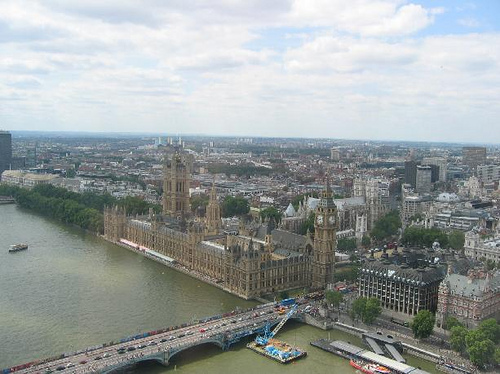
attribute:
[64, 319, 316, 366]
bridge — busy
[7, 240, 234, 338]
river — volumous, green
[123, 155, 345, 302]
castle — majestic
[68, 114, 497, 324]
city — london, large, aerial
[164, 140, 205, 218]
tower — high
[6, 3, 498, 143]
sky — overcast, cloudy, blue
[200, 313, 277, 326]
cars — crossing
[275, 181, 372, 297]
building — gray, brick, old, crowded, dark, parliament house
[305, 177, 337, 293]
clock tower — old, big ben, tall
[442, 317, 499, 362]
trees — growing